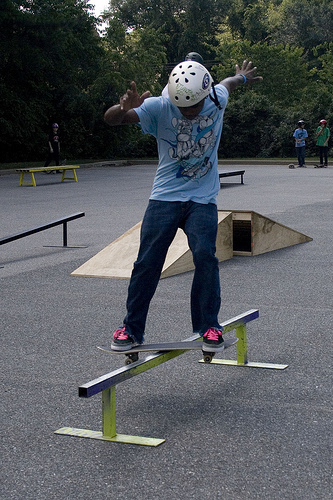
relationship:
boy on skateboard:
[104, 60, 265, 353] [95, 334, 240, 363]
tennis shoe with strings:
[201, 329, 224, 352] [201, 329, 223, 343]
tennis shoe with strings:
[111, 324, 138, 348] [112, 327, 132, 341]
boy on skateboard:
[293, 120, 308, 168] [292, 161, 307, 170]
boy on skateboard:
[315, 119, 331, 167] [311, 161, 327, 170]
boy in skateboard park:
[104, 60, 265, 353] [4, 149, 332, 495]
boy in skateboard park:
[293, 120, 308, 168] [4, 149, 332, 495]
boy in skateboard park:
[315, 119, 331, 167] [4, 149, 332, 495]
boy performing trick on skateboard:
[104, 60, 265, 353] [86, 333, 252, 367]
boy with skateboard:
[104, 60, 265, 353] [92, 334, 240, 366]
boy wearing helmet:
[104, 60, 265, 353] [156, 55, 211, 107]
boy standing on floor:
[293, 120, 308, 168] [282, 161, 332, 200]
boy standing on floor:
[315, 119, 331, 167] [282, 161, 332, 200]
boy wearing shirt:
[104, 60, 265, 353] [132, 83, 229, 205]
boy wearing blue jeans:
[104, 60, 265, 353] [124, 196, 224, 343]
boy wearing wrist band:
[104, 60, 265, 353] [236, 64, 248, 86]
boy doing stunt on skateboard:
[293, 120, 308, 168] [93, 334, 236, 355]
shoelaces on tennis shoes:
[202, 328, 222, 343] [111, 330, 313, 353]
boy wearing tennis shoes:
[104, 60, 265, 353] [111, 330, 313, 353]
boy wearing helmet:
[104, 60, 265, 353] [165, 60, 213, 107]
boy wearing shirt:
[315, 119, 331, 167] [315, 126, 330, 146]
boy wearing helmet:
[315, 119, 331, 167] [316, 117, 331, 127]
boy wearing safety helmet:
[293, 120, 308, 168] [296, 120, 304, 124]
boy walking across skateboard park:
[44, 123, 63, 173] [4, 149, 332, 495]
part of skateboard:
[55, 426, 168, 450] [96, 337, 240, 367]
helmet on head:
[165, 60, 213, 107] [161, 61, 213, 120]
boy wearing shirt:
[99, 57, 257, 350] [135, 85, 230, 208]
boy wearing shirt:
[290, 116, 308, 166] [292, 128, 308, 147]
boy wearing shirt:
[45, 121, 63, 173] [47, 131, 60, 147]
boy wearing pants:
[45, 121, 63, 173] [41, 148, 61, 166]